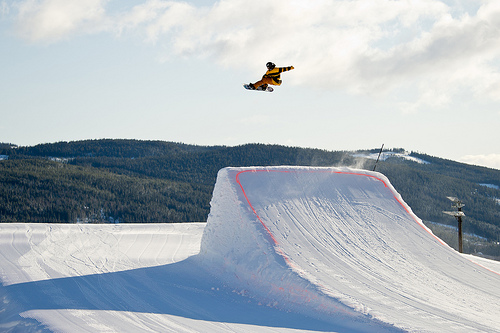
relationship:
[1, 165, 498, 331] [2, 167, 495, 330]
ground covered in snow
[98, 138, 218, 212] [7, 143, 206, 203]
hills covered in trees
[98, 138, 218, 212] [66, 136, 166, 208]
hills covered with trees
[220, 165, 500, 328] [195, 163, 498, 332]
lines on ramp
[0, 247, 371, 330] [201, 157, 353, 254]
shadow to left of ramp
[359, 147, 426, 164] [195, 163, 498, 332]
snow above ramp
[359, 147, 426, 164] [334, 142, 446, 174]
snow among trees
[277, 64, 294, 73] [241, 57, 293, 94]
arm of snowboarder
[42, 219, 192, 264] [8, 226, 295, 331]
light reflection/snow on snow